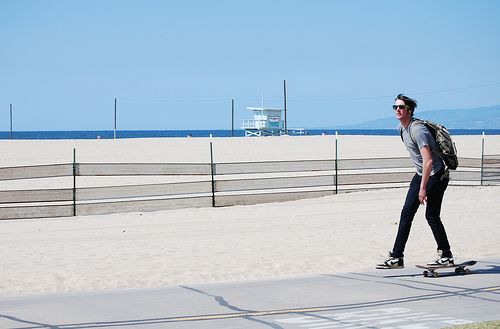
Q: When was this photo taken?
A: Outside, during the daytime.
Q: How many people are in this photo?
A: One.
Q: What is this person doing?
A: Skateboarding.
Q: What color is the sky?
A: Blue.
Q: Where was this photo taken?
A: Near a beach.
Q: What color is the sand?
A: Beige.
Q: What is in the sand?
A: A fence.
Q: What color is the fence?
A: Black.